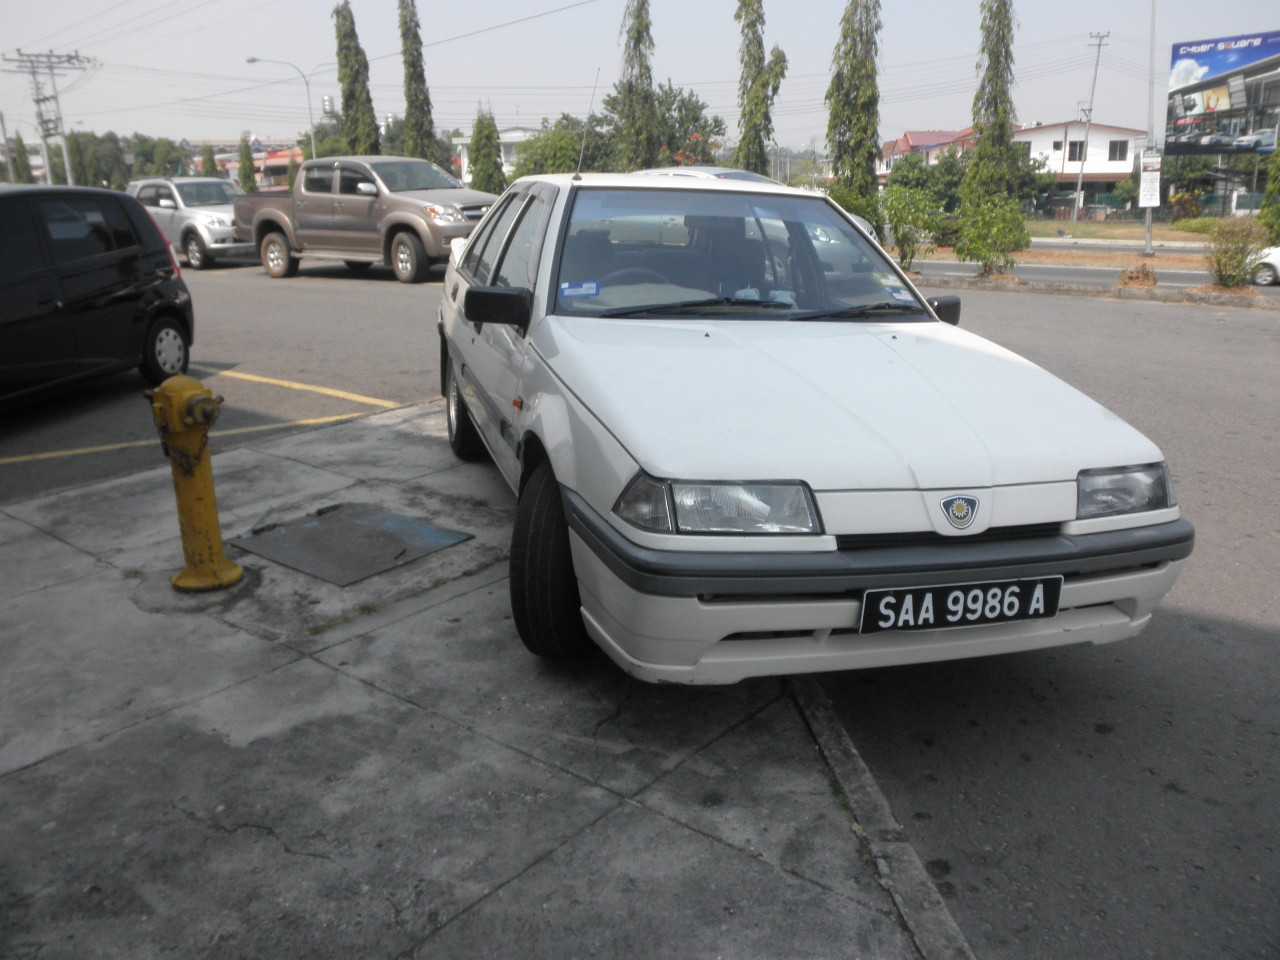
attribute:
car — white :
[439, 159, 1200, 717]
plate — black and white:
[865, 576, 1065, 636]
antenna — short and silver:
[558, 27, 602, 189]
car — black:
[8, 183, 224, 427]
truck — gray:
[239, 159, 504, 284]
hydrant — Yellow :
[146, 369, 253, 601]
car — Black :
[1, 180, 201, 431]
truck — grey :
[230, 150, 499, 278]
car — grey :
[127, 176, 248, 269]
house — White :
[883, 115, 1157, 219]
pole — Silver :
[15, 62, 87, 192]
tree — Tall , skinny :
[944, 66, 1023, 280]